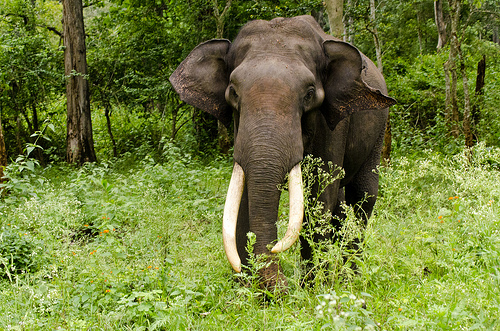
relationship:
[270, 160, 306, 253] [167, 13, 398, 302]
tusk on elephant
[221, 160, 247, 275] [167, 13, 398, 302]
tusk on elephant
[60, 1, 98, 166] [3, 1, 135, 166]
trunk of tree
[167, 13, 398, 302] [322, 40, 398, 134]
elephant has ear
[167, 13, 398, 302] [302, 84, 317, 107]
elephant has eye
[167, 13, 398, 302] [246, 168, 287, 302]
elephant has trunk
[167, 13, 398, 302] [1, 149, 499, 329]
elephant in brush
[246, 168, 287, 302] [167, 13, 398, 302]
trunk on elephant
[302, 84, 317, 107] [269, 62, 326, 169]
eye on side of head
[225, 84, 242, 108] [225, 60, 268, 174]
eye on side of head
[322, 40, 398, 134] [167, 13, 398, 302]
ear on elephant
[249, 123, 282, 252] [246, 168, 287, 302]
wrinkles on trunk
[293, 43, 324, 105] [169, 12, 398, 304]
temples on head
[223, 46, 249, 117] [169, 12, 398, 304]
temple on head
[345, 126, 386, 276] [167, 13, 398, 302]
back leg of elephant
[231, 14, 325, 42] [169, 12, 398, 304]
bumpy top of head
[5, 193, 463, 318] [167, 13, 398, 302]
flowers left of elephant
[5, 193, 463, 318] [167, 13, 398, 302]
flowers on right of elephant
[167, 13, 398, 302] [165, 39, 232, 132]
elephant has ear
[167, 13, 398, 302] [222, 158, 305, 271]
elephant with tusks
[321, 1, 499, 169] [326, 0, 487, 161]
trees have trunks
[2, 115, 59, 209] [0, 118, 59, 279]
leaves on plant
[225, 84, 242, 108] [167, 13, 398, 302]
eye on elephant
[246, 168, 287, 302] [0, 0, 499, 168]
trunk reaches area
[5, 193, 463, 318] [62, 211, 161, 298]
flowers on plant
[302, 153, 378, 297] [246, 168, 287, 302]
plant as tall as trunk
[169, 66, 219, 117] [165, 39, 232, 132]
spots on ear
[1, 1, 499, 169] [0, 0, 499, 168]
leaves on trees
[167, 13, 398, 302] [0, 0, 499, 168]
elephant on area